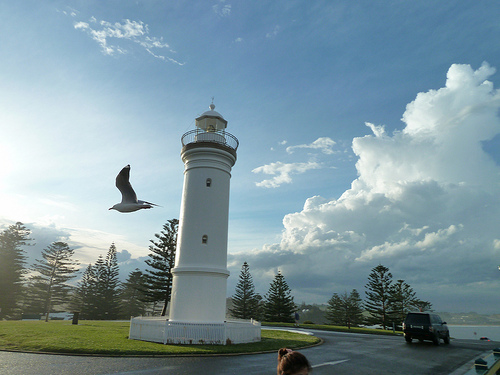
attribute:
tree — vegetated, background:
[360, 260, 400, 332]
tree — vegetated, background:
[389, 273, 416, 329]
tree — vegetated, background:
[262, 262, 303, 327]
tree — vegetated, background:
[226, 252, 267, 321]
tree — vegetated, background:
[133, 212, 184, 320]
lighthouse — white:
[168, 95, 238, 322]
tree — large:
[364, 262, 395, 327]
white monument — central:
[169, 98, 234, 323]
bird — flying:
[101, 157, 158, 229]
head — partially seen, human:
[276, 344, 308, 374]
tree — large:
[25, 216, 159, 338]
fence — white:
[129, 314, 262, 344]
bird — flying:
[78, 166, 190, 244]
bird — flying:
[105, 160, 157, 215]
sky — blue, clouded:
[1, 0, 498, 310]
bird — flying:
[104, 129, 176, 245]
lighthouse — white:
[114, 93, 261, 344]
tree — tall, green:
[366, 261, 397, 336]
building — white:
[132, 106, 262, 345]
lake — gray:
[449, 323, 499, 339]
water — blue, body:
[298, 257, 493, 374]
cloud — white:
[247, 154, 315, 189]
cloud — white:
[258, 61, 498, 296]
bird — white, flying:
[79, 159, 183, 246]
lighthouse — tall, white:
[153, 94, 245, 347]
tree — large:
[227, 254, 264, 318]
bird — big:
[105, 162, 161, 214]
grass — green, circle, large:
[0, 320, 320, 355]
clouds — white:
[42, 1, 204, 88]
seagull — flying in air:
[95, 159, 152, 209]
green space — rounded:
[18, 301, 315, 371]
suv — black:
[401, 306, 451, 345]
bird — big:
[107, 155, 158, 222]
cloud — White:
[254, 156, 321, 198]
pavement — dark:
[309, 330, 499, 374]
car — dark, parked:
[399, 307, 454, 349]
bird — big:
[108, 162, 155, 214]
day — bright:
[4, 3, 418, 334]